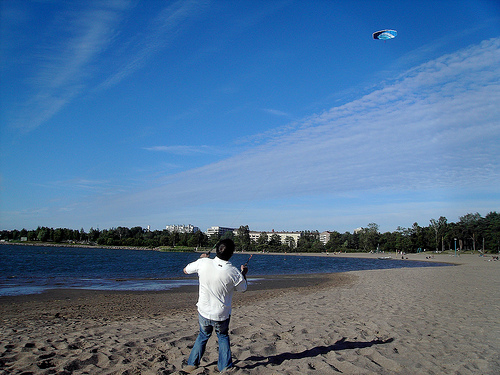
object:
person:
[183, 237, 250, 375]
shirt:
[184, 256, 248, 321]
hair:
[215, 238, 235, 260]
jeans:
[186, 314, 233, 368]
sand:
[0, 250, 499, 374]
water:
[1, 242, 464, 294]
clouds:
[131, 36, 500, 233]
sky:
[0, 0, 500, 235]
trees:
[437, 210, 500, 251]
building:
[200, 224, 327, 248]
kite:
[372, 26, 397, 44]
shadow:
[202, 335, 398, 374]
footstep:
[160, 345, 186, 361]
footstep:
[125, 340, 142, 351]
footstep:
[147, 342, 163, 351]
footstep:
[34, 357, 56, 371]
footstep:
[67, 343, 84, 353]